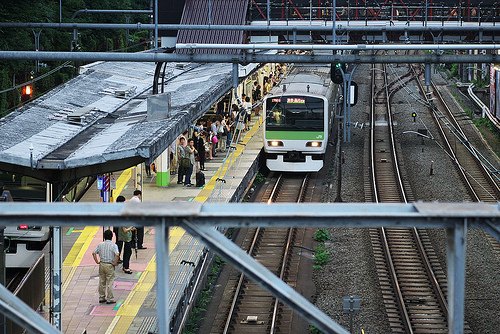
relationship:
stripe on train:
[265, 130, 323, 141] [263, 49, 336, 172]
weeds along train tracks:
[312, 226, 333, 270] [223, 173, 309, 334]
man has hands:
[93, 229, 121, 304] [92, 251, 123, 265]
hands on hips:
[92, 251, 123, 265] [97, 264, 116, 275]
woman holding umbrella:
[119, 226, 134, 275] [133, 227, 139, 262]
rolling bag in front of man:
[195, 159, 206, 188] [184, 138, 197, 185]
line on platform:
[60, 114, 133, 334] [0, 44, 298, 332]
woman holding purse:
[207, 122, 214, 162] [211, 137, 218, 144]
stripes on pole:
[103, 171, 111, 191] [103, 171, 112, 242]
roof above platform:
[0, 39, 281, 183] [0, 44, 298, 332]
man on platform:
[93, 229, 121, 304] [0, 44, 298, 332]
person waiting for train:
[178, 137, 187, 184] [263, 49, 336, 172]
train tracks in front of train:
[223, 173, 309, 334] [263, 49, 336, 172]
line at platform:
[60, 114, 133, 334] [0, 44, 298, 332]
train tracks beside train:
[371, 51, 499, 332] [263, 49, 336, 172]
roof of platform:
[0, 39, 281, 183] [0, 44, 298, 332]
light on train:
[267, 139, 282, 149] [263, 49, 336, 172]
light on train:
[307, 141, 321, 148] [263, 49, 336, 172]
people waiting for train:
[179, 105, 240, 188] [263, 49, 336, 172]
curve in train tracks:
[387, 62, 420, 98] [371, 51, 499, 332]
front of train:
[261, 97, 329, 172] [263, 49, 336, 172]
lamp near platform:
[25, 85, 31, 95] [0, 44, 298, 332]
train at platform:
[263, 49, 336, 172] [0, 44, 298, 332]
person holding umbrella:
[119, 226, 134, 275] [133, 227, 139, 262]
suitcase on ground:
[195, 169, 206, 187] [33, 107, 264, 322]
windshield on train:
[265, 99, 325, 131] [263, 49, 336, 172]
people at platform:
[179, 105, 240, 188] [0, 44, 298, 332]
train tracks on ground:
[223, 173, 309, 334] [185, 48, 498, 323]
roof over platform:
[0, 39, 281, 183] [0, 44, 298, 332]